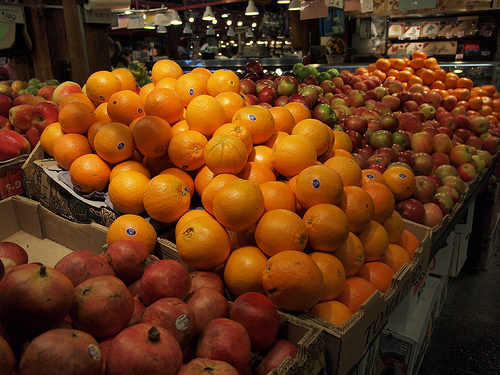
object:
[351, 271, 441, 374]
shelf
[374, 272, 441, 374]
boxes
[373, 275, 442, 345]
table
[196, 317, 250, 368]
pomengrantes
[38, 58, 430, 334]
pile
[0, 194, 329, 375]
carton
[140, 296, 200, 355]
pomegranate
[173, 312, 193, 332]
sticker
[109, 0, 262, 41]
many lights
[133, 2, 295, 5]
ceiling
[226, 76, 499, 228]
piles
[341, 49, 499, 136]
piles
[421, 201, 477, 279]
boxes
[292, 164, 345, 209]
orange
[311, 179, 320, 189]
blue sticker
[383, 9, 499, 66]
shelfs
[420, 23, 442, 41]
boxed items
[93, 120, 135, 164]
navel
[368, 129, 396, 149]
green and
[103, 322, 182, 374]
pomegranets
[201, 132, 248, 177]
oranges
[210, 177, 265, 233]
fruit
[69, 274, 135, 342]
pomegranete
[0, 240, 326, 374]
display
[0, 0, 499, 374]
background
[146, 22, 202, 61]
workers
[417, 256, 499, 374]
floor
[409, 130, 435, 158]
apples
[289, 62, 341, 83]
granny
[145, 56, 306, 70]
counter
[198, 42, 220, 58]
basket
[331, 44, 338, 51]
flowers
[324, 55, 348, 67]
basket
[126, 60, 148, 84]
bananas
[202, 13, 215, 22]
white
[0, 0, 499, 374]
indoor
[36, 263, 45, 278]
stem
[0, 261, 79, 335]
pomegranate